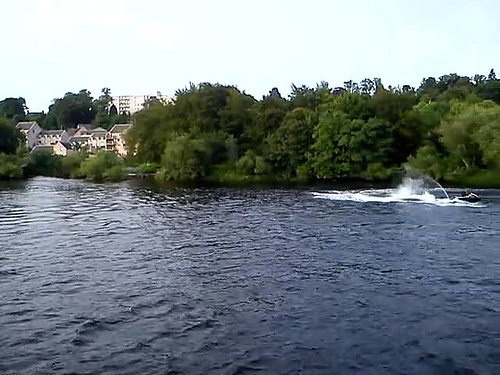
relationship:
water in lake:
[64, 175, 407, 356] [75, 209, 442, 360]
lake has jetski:
[75, 209, 442, 360] [340, 151, 467, 203]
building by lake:
[31, 99, 162, 152] [75, 209, 442, 360]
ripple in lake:
[102, 201, 415, 315] [75, 209, 442, 360]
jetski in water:
[340, 151, 467, 203] [64, 175, 407, 356]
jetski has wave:
[340, 151, 467, 203] [309, 162, 411, 212]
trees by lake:
[133, 73, 365, 162] [75, 209, 442, 360]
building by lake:
[104, 121, 142, 159] [75, 209, 442, 360]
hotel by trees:
[95, 80, 180, 110] [133, 73, 365, 162]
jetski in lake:
[340, 151, 467, 203] [75, 209, 442, 360]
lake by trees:
[75, 209, 442, 360] [133, 73, 365, 162]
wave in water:
[309, 162, 411, 212] [64, 175, 407, 356]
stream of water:
[150, 166, 314, 225] [64, 175, 407, 356]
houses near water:
[30, 100, 224, 222] [64, 175, 407, 356]